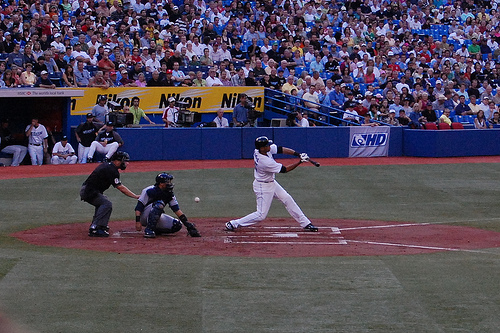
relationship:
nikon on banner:
[221, 94, 262, 109] [55, 87, 266, 116]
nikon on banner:
[159, 93, 202, 113] [55, 87, 266, 116]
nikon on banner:
[97, 94, 140, 115] [55, 87, 266, 116]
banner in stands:
[55, 87, 266, 116] [1, 2, 499, 129]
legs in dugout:
[6, 144, 26, 168] [3, 97, 74, 160]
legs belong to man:
[6, 144, 26, 168] [0, 119, 26, 167]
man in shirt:
[127, 97, 156, 127] [126, 107, 145, 126]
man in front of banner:
[127, 97, 156, 127] [55, 87, 266, 116]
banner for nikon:
[55, 87, 266, 116] [221, 94, 262, 109]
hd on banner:
[367, 132, 388, 148] [349, 125, 391, 157]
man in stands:
[467, 37, 480, 55] [1, 2, 499, 129]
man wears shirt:
[467, 37, 480, 55] [464, 46, 482, 52]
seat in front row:
[455, 117, 473, 129] [411, 113, 499, 130]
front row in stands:
[411, 113, 499, 130] [1, 2, 499, 129]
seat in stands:
[455, 117, 473, 129] [1, 2, 499, 129]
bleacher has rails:
[1, 2, 499, 129] [262, 89, 393, 129]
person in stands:
[175, 12, 187, 35] [1, 2, 499, 129]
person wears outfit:
[175, 12, 187, 35] [173, 19, 189, 37]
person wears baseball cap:
[162, 70, 174, 88] [165, 68, 172, 75]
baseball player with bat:
[226, 137, 319, 232] [309, 160, 320, 170]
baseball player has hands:
[226, 137, 319, 232] [299, 154, 309, 163]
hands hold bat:
[299, 154, 309, 163] [309, 160, 320, 170]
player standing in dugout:
[24, 117, 49, 165] [3, 97, 74, 160]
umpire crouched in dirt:
[78, 151, 142, 237] [10, 216, 499, 256]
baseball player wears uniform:
[226, 137, 319, 232] [231, 144, 311, 230]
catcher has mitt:
[135, 173, 201, 239] [186, 224, 199, 238]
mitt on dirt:
[186, 224, 199, 238] [10, 216, 499, 256]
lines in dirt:
[226, 220, 494, 258] [10, 216, 499, 256]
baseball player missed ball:
[226, 137, 319, 232] [193, 196, 201, 205]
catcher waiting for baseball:
[135, 173, 201, 239] [193, 196, 201, 205]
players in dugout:
[0, 113, 121, 166] [3, 97, 74, 160]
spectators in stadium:
[2, 1, 499, 129] [0, 1, 499, 166]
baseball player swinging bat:
[226, 137, 319, 232] [309, 160, 320, 170]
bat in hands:
[309, 160, 320, 170] [299, 154, 309, 163]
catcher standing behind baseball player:
[135, 173, 201, 239] [226, 137, 319, 232]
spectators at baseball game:
[2, 1, 499, 129] [0, 158, 499, 332]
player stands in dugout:
[24, 117, 49, 165] [3, 97, 74, 160]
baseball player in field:
[226, 137, 319, 232] [0, 164, 498, 333]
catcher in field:
[135, 173, 201, 239] [0, 164, 498, 333]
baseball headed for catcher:
[193, 196, 201, 205] [135, 173, 201, 239]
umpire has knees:
[78, 151, 142, 237] [98, 201, 113, 213]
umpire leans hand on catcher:
[78, 151, 142, 237] [135, 173, 201, 239]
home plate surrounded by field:
[270, 231, 297, 239] [0, 164, 498, 333]